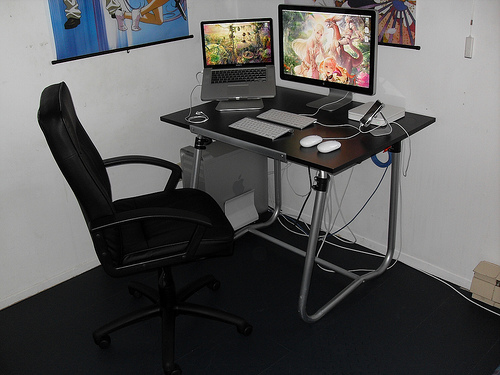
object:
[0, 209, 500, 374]
floor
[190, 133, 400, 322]
legs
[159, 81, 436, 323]
desk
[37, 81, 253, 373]
chair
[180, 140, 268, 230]
apple computer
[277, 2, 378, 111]
imac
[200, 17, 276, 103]
macbook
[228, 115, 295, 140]
keyboard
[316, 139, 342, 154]
mouse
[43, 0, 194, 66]
poster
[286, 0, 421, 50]
poster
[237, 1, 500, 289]
wall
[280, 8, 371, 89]
screen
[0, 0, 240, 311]
wall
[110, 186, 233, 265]
seat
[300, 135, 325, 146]
mouse